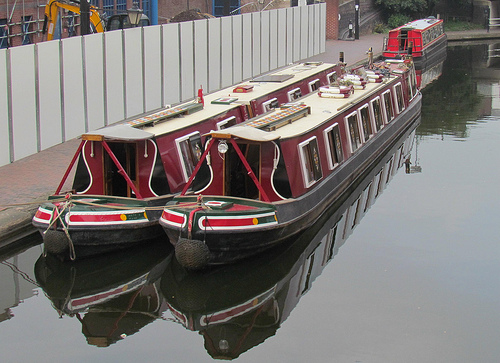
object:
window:
[297, 139, 327, 186]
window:
[328, 124, 345, 163]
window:
[344, 109, 364, 156]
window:
[181, 130, 212, 184]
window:
[381, 87, 399, 126]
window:
[362, 104, 377, 141]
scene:
[0, 0, 500, 362]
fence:
[0, 1, 329, 172]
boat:
[380, 18, 448, 60]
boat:
[217, 140, 232, 156]